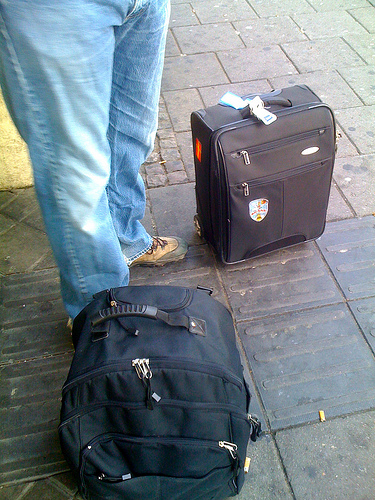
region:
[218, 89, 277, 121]
Tags on suitcase handle.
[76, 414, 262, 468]
Black bag sitting on ground.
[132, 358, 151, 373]
Silver zippers on bag.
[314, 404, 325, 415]
Cigarette butt on ground.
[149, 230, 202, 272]
Person wearing brown shoes.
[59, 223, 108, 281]
Person wearing blue jeans.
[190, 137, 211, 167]
Red and yellow patch on suitcase.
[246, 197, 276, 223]
White patch on suitcase.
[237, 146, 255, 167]
Silver zipper on suitcase.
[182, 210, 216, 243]
Black and silver wheel on suitcase.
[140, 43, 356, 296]
a suitcase on the ground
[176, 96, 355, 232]
a black suitcase on teh ground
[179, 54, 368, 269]
a rolling suitcase ont he ground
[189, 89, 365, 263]
a black rolling suitcase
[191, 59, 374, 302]
a black rolling suitcase on the ground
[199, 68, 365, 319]
a suitcase with tags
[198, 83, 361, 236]
a black suitcase with tag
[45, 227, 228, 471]
a backpack on ground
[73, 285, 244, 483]
a black backpack on the ground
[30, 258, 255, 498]
a black back pack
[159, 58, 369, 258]
suitcase on the ground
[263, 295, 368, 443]
lines on the ground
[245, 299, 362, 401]
dark ground under the objects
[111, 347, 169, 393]
zippers on the backpack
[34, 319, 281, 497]
black backpack in photo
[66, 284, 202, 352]
handle on top of backpack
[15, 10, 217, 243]
blue jeans on the person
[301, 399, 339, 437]
item on the ground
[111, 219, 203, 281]
shoe on man's foot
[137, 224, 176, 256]
laces on the shoe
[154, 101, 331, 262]
black bag on ground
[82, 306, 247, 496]
black backpack on ground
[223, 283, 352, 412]
black and metal tiles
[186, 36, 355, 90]
grey tile on sidewalk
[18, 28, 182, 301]
person has blue pants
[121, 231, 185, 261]
brown and black shoes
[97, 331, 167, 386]
metal zippers on bag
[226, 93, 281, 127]
white tag on bag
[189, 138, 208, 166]
orange tag on bag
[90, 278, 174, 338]
black handle on backpack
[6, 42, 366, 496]
a brick and stone sidewalk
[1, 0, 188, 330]
person in faded jeans and brown shoes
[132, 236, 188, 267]
brown left shoes with brown laces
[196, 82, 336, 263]
black suitcase standing up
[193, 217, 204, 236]
wheel on the suitcase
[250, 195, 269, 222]
shield patch on suitcase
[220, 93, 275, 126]
tags on suitcase handle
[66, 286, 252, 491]
black duffle bag on the left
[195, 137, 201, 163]
orange sticker on side of suitcase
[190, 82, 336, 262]
small black rolling suitcase